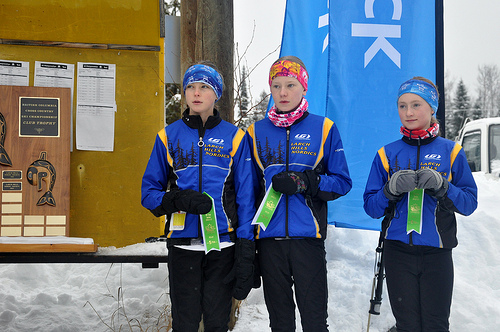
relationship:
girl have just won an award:
[138, 60, 257, 329] [197, 190, 222, 253]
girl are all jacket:
[139, 60, 256, 332] [156, 110, 391, 237]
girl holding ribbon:
[139, 60, 256, 332] [191, 190, 227, 256]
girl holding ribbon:
[235, 55, 351, 332] [250, 178, 285, 234]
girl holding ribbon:
[362, 76, 477, 332] [403, 183, 427, 237]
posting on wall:
[0, 58, 31, 88] [0, 39, 168, 250]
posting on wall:
[31, 53, 78, 156] [0, 39, 168, 250]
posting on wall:
[74, 54, 118, 155] [0, 39, 168, 250]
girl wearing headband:
[389, 76, 451, 146] [396, 82, 436, 102]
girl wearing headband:
[138, 60, 257, 329] [178, 60, 223, 97]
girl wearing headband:
[235, 55, 351, 332] [259, 58, 309, 92]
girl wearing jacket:
[362, 76, 477, 332] [371, 138, 456, 233]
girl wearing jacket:
[242, 51, 352, 330] [239, 100, 354, 240]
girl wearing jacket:
[138, 60, 257, 329] [137, 106, 252, 250]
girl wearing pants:
[362, 76, 477, 332] [382, 238, 454, 330]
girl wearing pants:
[242, 51, 352, 330] [250, 232, 330, 329]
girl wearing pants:
[138, 60, 257, 329] [160, 230, 245, 330]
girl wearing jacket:
[362, 76, 477, 332] [359, 129, 482, 251]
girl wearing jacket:
[138, 60, 257, 329] [139, 110, 258, 253]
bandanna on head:
[268, 60, 308, 91] [264, 57, 311, 127]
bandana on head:
[183, 64, 223, 103] [153, 52, 240, 136]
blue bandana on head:
[397, 80, 439, 116] [394, 72, 441, 132]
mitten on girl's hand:
[166, 182, 220, 222] [161, 184, 206, 212]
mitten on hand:
[230, 232, 262, 299] [229, 235, 259, 305]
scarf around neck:
[401, 121, 440, 138] [397, 119, 448, 147]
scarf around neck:
[269, 98, 307, 125] [275, 109, 301, 122]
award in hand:
[406, 186, 425, 235] [414, 162, 441, 192]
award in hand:
[251, 182, 284, 231] [263, 165, 321, 200]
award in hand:
[200, 191, 221, 255] [149, 181, 215, 219]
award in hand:
[200, 191, 221, 255] [175, 187, 212, 214]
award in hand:
[251, 182, 284, 231] [269, 164, 321, 198]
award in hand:
[406, 186, 425, 235] [382, 158, 445, 200]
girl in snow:
[139, 60, 256, 332] [9, 270, 152, 328]